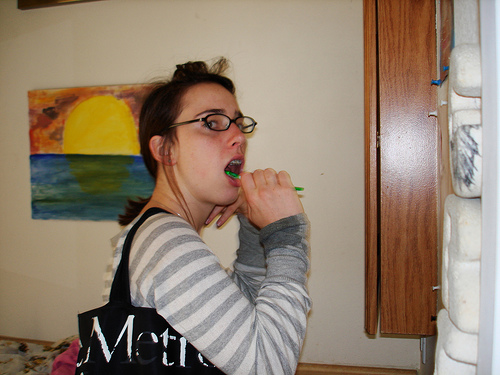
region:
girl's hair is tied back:
[123, 62, 220, 147]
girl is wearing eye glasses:
[165, 109, 265, 143]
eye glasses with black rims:
[146, 92, 289, 147]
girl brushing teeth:
[135, 87, 308, 209]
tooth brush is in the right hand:
[208, 155, 305, 216]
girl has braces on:
[203, 141, 258, 196]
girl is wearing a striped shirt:
[118, 201, 230, 318]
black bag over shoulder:
[86, 212, 244, 372]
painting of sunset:
[27, 75, 147, 221]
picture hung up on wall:
[22, 78, 173, 223]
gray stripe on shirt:
[194, 305, 246, 352]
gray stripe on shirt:
[260, 295, 310, 353]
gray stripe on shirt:
[163, 219, 191, 251]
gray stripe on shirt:
[133, 215, 164, 243]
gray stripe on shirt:
[103, 245, 136, 287]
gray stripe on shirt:
[151, 213, 177, 247]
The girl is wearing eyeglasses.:
[170, 114, 257, 131]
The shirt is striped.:
[147, 230, 192, 304]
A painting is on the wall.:
[30, 83, 114, 220]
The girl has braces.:
[227, 157, 247, 167]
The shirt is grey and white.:
[150, 242, 201, 306]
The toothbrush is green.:
[227, 170, 240, 180]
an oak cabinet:
[339, 13, 429, 352]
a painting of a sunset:
[18, 63, 135, 228]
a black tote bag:
[32, 257, 163, 373]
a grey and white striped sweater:
[160, 234, 297, 352]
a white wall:
[272, 32, 357, 136]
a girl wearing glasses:
[138, 66, 277, 203]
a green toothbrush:
[225, 168, 242, 183]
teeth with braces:
[225, 150, 267, 170]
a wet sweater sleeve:
[242, 201, 329, 258]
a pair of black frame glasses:
[173, 114, 258, 134]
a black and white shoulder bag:
[73, 208, 230, 373]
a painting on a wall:
[23, 81, 137, 229]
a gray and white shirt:
[109, 212, 317, 370]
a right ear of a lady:
[148, 133, 173, 167]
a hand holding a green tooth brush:
[221, 162, 311, 216]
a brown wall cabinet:
[366, 4, 435, 339]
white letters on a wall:
[431, 53, 489, 357]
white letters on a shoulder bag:
[75, 319, 225, 369]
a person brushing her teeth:
[66, 51, 336, 366]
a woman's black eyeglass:
[155, 106, 264, 133]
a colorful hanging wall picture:
[24, 81, 164, 222]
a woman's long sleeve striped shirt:
[101, 215, 318, 373]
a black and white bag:
[72, 208, 217, 373]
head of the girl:
[133, 67, 270, 216]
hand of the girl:
[215, 149, 316, 262]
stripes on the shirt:
[141, 227, 278, 349]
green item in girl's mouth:
[218, 160, 311, 212]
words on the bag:
[51, 263, 218, 373]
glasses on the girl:
[188, 110, 265, 143]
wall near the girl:
[306, 129, 361, 204]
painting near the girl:
[0, 68, 152, 251]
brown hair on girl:
[113, 53, 241, 118]